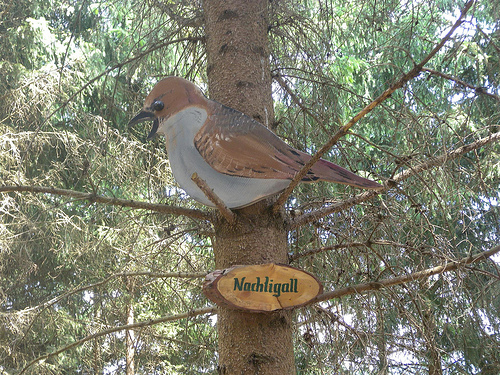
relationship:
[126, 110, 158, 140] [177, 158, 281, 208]
open beak on belly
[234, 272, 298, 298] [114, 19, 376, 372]
nachligall made of tree.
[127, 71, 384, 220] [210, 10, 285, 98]
bird in tree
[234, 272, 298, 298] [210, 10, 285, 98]
nachligall in tree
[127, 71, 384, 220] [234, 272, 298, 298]
bird with nachligall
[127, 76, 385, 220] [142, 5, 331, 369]
bird in tree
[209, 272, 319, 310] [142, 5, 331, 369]
name plate in tree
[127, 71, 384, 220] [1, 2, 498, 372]
bird on tree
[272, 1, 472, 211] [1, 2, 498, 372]
branch on tree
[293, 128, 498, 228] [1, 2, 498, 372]
branch on tree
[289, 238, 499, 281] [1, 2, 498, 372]
branch on tree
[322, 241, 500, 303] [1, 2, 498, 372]
branch on tree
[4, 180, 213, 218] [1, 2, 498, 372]
branch on tree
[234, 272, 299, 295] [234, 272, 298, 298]
nachligall on nachligall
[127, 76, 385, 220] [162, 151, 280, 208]
bird has belly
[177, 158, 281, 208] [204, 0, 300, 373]
belly on tree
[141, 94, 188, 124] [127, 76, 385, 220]
eye on bird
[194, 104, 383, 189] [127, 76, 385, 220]
brown feathers on bird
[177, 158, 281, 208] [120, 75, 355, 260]
belly on bird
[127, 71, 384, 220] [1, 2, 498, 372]
bird in tree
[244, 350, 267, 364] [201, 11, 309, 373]
sap dripping from tree